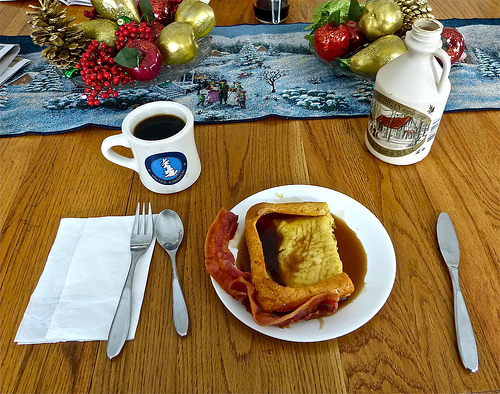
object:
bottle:
[364, 19, 451, 165]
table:
[0, 0, 500, 394]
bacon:
[204, 202, 354, 329]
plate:
[209, 186, 396, 343]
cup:
[101, 101, 201, 194]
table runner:
[0, 17, 500, 135]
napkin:
[19, 213, 154, 346]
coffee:
[133, 114, 186, 141]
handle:
[452, 285, 477, 373]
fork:
[106, 199, 153, 359]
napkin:
[13, 214, 156, 345]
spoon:
[154, 209, 188, 336]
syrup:
[236, 210, 367, 327]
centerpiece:
[25, 0, 214, 105]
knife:
[436, 211, 478, 374]